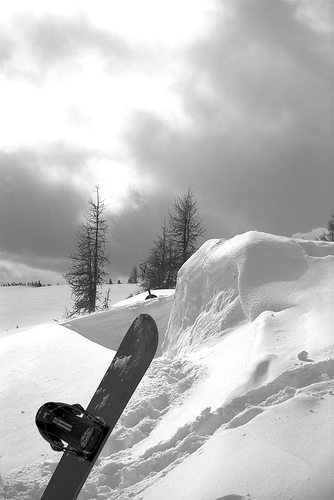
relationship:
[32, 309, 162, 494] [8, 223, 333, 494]
snowboard in snow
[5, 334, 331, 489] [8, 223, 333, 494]
tracks in snow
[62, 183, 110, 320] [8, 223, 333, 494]
trees in snow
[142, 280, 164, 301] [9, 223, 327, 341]
handle in distance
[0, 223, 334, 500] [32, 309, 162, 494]
snow on snowboard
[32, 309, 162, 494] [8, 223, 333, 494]
snowboard standing in snow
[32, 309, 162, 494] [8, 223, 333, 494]
snowboard up in snow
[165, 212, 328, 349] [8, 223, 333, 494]
rock covered in snow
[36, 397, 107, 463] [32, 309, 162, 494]
strap on snowboard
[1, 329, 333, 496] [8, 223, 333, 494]
foot prints in snow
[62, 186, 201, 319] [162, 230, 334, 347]
trees on hill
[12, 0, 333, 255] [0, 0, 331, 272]
clouds in skies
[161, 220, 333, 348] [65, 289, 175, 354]
hill makes shadow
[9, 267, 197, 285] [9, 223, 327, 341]
forest in distance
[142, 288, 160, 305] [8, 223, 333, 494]
shovel in snow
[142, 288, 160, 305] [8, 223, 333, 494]
shovel stuck in snow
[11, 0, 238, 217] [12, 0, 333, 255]
sun through clouds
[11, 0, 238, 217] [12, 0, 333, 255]
sun breaks through clouds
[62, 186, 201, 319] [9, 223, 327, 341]
trees on hillside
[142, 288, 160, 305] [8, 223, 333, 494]
shovel out of snow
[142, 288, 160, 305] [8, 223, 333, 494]
shovel sticking out of snow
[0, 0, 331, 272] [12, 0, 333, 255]
skies with clouds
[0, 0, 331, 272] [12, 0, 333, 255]
skies filled with clouds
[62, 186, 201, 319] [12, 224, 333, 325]
trees on ridge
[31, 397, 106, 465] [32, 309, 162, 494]
boot attached to snowboard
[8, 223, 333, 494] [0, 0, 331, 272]
snow under skies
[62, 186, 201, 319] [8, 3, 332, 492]
trees in photograph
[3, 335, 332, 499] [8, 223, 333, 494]
sets in snow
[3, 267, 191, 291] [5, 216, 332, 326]
trees on horizon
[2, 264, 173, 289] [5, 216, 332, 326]
line on horizon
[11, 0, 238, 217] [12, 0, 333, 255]
sun though clouds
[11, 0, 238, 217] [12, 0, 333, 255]
sun peeking through clouds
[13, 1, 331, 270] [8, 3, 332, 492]
skies in photograph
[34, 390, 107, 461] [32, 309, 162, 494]
holder on snowboard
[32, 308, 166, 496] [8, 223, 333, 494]
something in snow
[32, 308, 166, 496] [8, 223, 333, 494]
something standing in snow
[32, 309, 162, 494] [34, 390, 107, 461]
snowboard with holder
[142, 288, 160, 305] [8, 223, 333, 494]
shovel into snow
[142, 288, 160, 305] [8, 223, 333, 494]
shovel stuck into snow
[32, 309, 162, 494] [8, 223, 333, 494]
snowboard stuck in snow